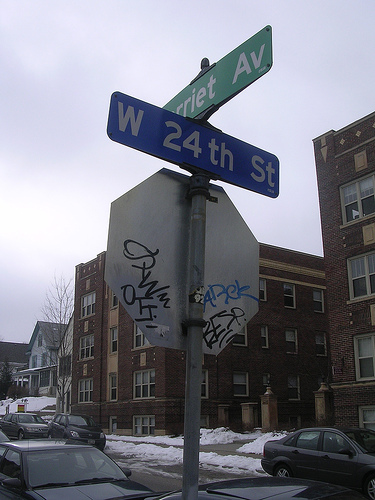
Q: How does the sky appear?
A: Overcast.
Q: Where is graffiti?
A: On back of a sign.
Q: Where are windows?
A: On the buildings.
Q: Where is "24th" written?
A: On blue sign.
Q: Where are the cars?
A: On the road.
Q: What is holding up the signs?
A: A gray pole.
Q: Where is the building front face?
A: The street.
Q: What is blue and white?
A: The sign.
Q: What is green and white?
A: The sign.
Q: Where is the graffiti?
A: Back of sign.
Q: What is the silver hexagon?
A: Street sign.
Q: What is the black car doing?
A: Parking.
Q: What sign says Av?
A: Green and white.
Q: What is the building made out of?
A: Brick.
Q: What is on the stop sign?
A: Graffiti.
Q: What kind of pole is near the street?
A: A metal pole.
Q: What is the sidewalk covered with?
A: Snow.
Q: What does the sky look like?
A: Gray and cloudy.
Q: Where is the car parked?
A: Near a stop sign.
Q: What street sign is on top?
A: Harriet Ave.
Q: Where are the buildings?
A: Across street.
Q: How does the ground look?
A: White.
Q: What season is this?
A: Winter.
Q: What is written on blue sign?
A: W 24th St.